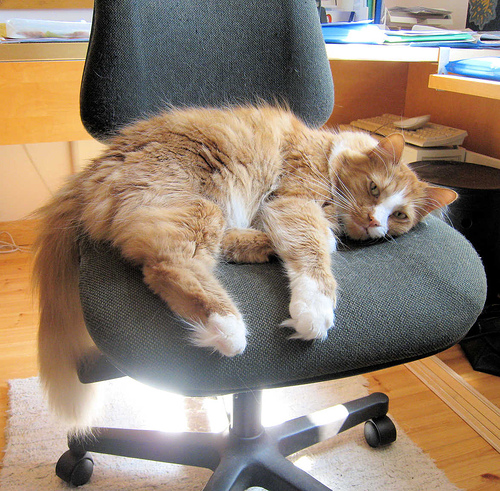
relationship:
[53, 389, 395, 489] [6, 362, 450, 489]
base on rug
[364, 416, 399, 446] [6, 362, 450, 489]
wheel on rug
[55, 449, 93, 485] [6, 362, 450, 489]
wheel on rug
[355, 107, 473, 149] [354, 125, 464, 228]
white keyboard on box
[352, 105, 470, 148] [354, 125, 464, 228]
mouse on box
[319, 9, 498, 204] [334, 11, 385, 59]
desk filled with paper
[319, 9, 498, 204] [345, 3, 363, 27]
desk filled with pen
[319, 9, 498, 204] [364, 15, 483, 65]
desk filled with notebook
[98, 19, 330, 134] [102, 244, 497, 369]
fabric on chair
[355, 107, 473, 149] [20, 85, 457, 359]
white keyboard behind cat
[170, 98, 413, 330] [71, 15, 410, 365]
cat on a chair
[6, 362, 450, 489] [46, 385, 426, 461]
rug on floor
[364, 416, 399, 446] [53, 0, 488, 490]
wheel on chair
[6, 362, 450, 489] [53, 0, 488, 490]
rug under chair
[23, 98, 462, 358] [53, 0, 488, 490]
cat on chair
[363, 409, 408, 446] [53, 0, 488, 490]
casters on chair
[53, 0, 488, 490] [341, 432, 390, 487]
chair on rug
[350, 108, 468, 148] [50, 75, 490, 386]
keyboard behind cat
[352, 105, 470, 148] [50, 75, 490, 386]
mouse behind cat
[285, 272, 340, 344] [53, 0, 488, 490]
cat paws on chair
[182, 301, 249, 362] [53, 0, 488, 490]
cat paws on chair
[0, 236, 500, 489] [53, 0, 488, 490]
floor under chair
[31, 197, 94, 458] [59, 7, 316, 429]
fluffy tail on chair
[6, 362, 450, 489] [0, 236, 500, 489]
rug on floor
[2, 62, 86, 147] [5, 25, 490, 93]
wall under desk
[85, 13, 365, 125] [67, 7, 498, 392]
backrest on chair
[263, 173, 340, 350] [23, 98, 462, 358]
arm of cat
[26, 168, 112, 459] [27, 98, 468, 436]
tail of cat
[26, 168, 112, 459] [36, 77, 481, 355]
tail of cat